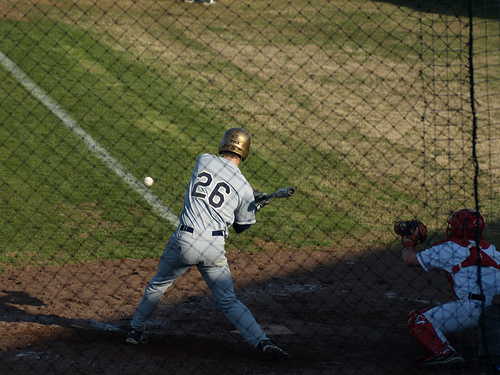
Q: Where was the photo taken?
A: At the ball field.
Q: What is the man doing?
A: Hitting the baseball.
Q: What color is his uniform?
A: Light blue.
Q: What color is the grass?
A: Green.